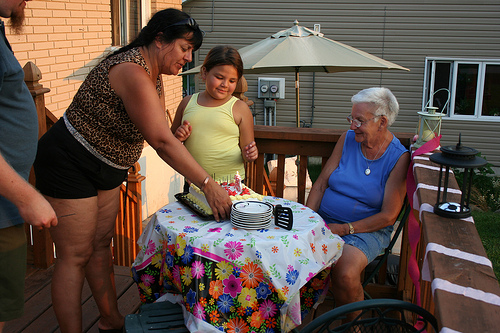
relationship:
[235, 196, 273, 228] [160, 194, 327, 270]
plate on table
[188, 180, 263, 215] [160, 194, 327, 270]
cake on table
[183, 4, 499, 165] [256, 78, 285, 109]
building has a meter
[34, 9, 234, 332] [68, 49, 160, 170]
woman has a shirt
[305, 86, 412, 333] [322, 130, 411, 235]
woman has a shirt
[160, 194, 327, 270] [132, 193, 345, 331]
table has a cloth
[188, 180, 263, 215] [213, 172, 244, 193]
cake for a birthday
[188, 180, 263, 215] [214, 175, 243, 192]
cake has candles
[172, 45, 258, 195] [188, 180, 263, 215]
girl looking at cake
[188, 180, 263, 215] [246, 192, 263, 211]
cake has slices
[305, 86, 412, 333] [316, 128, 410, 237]
woman wearing blue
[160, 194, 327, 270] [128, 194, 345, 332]
table has a tablecloth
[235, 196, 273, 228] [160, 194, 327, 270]
plate are on a table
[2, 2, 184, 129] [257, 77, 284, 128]
house has a utility box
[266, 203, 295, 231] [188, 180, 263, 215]
spatulla for cake